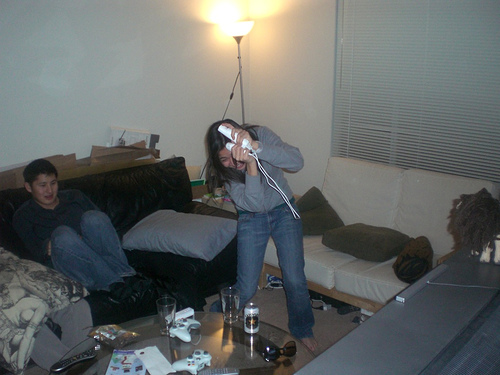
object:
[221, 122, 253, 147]
head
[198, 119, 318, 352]
girl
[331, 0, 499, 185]
blinds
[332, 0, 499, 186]
window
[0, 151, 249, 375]
couch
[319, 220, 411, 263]
pillow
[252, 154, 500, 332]
couch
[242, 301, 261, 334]
canned beverage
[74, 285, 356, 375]
coffee table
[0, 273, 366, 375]
ground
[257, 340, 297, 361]
sunglasses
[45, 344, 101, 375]
remote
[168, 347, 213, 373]
controller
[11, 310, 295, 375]
table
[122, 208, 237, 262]
grey pillow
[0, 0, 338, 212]
wall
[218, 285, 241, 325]
glass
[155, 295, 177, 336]
glass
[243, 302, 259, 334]
can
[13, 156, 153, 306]
guy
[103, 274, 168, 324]
feet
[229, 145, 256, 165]
hands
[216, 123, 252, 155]
remote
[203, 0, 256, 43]
lamp